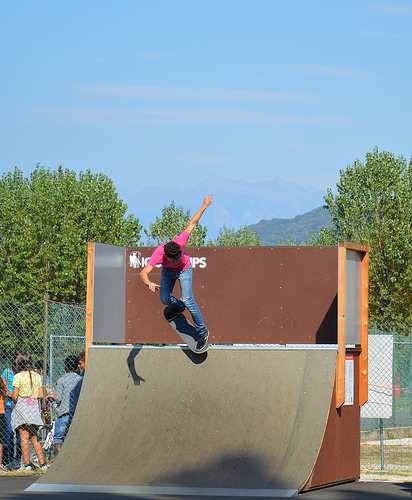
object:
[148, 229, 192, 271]
shirt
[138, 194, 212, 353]
skateboarder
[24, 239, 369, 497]
ramp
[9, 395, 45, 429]
jacket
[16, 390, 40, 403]
waist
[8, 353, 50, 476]
girl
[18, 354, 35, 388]
ponytail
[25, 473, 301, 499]
line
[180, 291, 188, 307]
hole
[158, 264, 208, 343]
skater's jeans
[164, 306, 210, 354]
skateboard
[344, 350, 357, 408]
sign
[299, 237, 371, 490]
side of ramp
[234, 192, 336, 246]
hill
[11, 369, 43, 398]
shirt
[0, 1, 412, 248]
sky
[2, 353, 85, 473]
people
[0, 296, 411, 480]
fence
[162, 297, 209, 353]
shoes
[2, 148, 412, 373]
trees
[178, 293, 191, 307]
tear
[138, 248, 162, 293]
arm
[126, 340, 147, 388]
shadow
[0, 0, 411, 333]
background